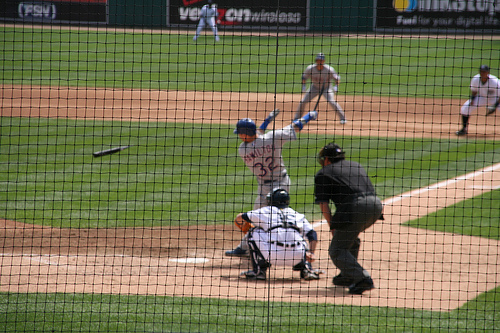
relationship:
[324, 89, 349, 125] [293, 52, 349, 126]
leg on person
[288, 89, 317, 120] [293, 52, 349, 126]
leg on person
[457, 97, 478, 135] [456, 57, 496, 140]
leg on person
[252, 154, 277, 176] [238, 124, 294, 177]
number on jersey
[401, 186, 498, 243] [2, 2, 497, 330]
grass on baseball field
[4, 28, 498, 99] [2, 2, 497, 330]
grass on baseball field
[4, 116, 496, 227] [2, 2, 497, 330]
grass on baseball field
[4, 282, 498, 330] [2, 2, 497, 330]
grass on baseball field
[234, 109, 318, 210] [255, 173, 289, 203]
batter wears grey pants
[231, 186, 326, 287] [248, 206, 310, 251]
catcher wears shirt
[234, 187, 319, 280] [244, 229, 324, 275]
catcher has white pants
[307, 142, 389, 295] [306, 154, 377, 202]
person has black shirt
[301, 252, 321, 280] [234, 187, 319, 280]
leg of a catcher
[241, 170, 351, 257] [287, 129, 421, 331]
leg of a person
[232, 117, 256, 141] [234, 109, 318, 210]
head of a batter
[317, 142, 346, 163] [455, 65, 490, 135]
head of a person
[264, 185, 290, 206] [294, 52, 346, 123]
head of a person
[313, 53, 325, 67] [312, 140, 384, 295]
head of a person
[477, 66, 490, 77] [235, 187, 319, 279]
head of a person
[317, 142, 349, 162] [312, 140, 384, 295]
head of a person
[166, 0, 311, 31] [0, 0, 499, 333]
banner on side of baseball baseball field